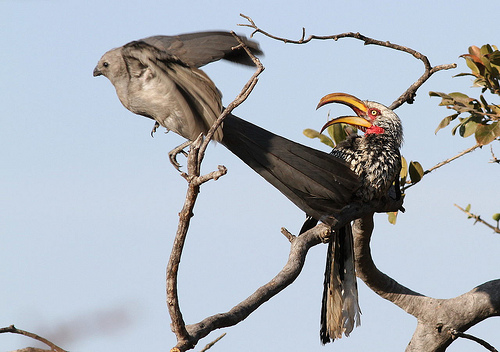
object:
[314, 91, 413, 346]
bird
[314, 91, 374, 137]
beak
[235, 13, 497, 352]
tree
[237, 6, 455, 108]
branch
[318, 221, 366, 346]
tail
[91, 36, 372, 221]
bird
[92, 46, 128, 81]
head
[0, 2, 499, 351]
sky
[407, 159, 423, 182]
leaves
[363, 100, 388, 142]
face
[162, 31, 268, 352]
branch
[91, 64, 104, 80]
beak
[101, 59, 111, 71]
eyeball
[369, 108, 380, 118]
eye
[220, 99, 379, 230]
tail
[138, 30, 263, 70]
wing